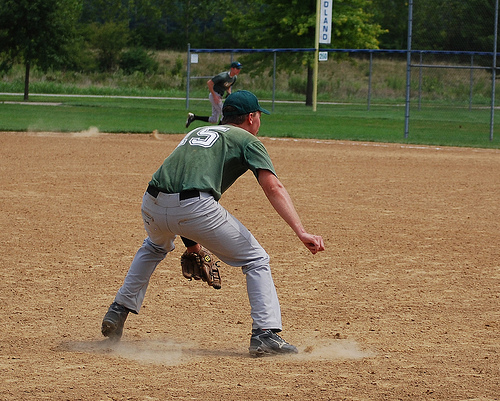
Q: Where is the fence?
A: Behind the grass in the distance.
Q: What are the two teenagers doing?
A: Playing baseball.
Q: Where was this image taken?
A: On a baseball field.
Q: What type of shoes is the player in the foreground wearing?
A: Cleats.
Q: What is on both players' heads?
A: Baseball caps.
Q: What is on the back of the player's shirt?
A: His number.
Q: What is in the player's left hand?
A: A baseball glove.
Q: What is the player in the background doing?
A: Running.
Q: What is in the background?
A: An overgrown field and trees.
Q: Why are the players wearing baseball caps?
A: To keep the sun out of their eyes.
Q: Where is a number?
A: On back of green shirt.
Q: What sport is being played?
A: Baseball.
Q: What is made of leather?
A: Glove.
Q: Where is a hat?
A: On player's head.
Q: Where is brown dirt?
A: On baseball field.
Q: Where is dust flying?
A: Around the player's feet.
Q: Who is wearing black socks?
A: Player in the background.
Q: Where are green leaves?
A: On trees.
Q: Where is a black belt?
A: Around player's waist.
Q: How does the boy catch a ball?
A: Glove.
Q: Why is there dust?
A: Dirt is disturbed.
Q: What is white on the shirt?
A: Number.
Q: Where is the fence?
A: Back right.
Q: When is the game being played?
A: Warm day.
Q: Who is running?
A: Boy in background.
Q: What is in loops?
A: Pants belt.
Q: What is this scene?
A: Baseball game.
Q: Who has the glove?
A: Catcher.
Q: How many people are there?
A: Two.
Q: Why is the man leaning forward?
A: Catching the ball.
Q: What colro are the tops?
A: Green.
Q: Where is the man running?
A: To bases.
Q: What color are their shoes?
A: Black.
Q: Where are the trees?
A: On the grass.